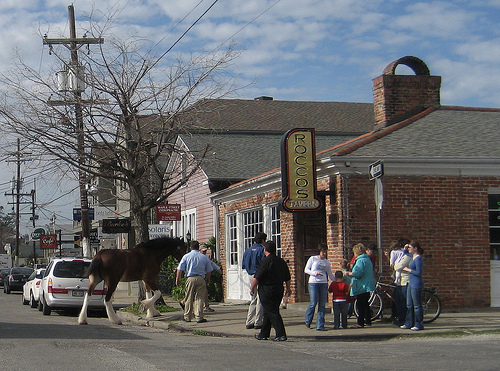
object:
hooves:
[76, 290, 173, 325]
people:
[175, 233, 445, 343]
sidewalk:
[163, 298, 500, 336]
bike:
[353, 278, 449, 322]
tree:
[0, 42, 259, 308]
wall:
[213, 176, 486, 307]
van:
[40, 255, 115, 318]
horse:
[75, 236, 187, 325]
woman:
[303, 247, 332, 330]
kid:
[330, 268, 349, 329]